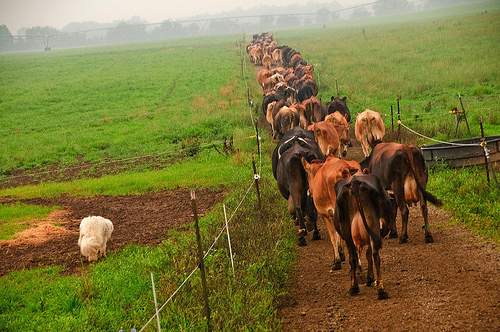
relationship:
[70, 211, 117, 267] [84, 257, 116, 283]
dog sniffs grass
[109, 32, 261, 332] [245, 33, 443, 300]
fence to left of herd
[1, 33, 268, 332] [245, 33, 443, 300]
field to left of herd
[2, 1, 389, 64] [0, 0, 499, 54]
cropdusters in fog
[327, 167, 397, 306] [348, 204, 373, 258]
cow has udder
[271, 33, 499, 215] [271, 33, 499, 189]
fence has posts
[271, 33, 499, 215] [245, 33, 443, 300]
fence to right of herd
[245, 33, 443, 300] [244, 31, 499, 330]
herd walk down trail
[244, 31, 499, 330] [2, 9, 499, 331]
trail bissects field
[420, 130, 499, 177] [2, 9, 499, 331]
tub in field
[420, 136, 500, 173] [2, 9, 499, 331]
tub in field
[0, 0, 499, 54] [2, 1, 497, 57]
fog in distance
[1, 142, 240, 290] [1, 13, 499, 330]
mud in grass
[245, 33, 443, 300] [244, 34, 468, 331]
herd in line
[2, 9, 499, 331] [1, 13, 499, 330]
field of grass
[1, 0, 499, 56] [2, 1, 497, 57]
trees in distance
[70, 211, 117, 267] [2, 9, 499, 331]
dog in field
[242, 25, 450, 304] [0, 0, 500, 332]
herd heading out to field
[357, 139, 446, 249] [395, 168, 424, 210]
cow has udder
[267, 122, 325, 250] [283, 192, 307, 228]
cow has udder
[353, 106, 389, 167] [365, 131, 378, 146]
cow has udder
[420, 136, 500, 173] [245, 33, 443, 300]
tub to right of herd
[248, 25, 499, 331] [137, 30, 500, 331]
cow path between fences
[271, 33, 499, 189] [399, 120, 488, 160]
posts connected with rope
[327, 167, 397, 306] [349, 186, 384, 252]
cow has tail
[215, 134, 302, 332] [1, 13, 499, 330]
dirt crosses into grass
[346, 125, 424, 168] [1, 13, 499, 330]
dirt crosses into grass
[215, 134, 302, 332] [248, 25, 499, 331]
dirt from cow path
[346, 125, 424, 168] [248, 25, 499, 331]
dirt from cow path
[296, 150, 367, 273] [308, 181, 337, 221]
cow has stomach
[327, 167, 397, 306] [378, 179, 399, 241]
cow has stomach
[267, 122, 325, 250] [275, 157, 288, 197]
cow has stomach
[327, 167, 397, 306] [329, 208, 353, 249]
cow has thigh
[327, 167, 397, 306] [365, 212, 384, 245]
cow has thigh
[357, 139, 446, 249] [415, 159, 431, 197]
cow has thigh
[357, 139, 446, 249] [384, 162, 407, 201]
cow has thigh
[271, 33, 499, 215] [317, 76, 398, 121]
fence connected with rope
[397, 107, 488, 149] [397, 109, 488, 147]
posts affixed with yellow fasteners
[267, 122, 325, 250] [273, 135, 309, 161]
cow has stripes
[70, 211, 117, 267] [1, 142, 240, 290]
dog snuffles in mud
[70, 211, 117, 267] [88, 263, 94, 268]
dog has found mysterious thing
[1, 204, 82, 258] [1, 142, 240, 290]
sand beside mud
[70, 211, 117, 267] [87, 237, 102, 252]
dog has ear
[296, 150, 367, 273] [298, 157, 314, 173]
cow has ear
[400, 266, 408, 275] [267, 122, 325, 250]
'turkerworker has heard of cow